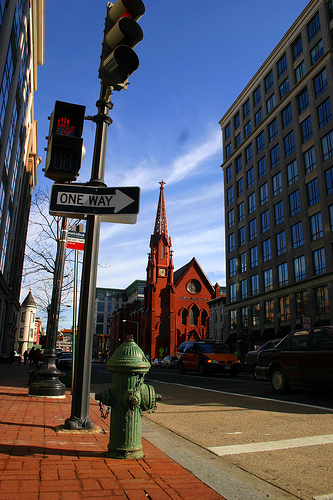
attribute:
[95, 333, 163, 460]
fire hydrant — green colored, green, green in color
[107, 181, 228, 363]
building — church, red colored, red, tall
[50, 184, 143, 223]
sign — black, one way, don't walk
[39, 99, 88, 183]
light — crosswalk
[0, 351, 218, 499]
sidewalk — brick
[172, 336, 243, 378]
minivan — orange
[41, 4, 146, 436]
pole — black, metal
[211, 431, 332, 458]
line — white in color, white colored, white